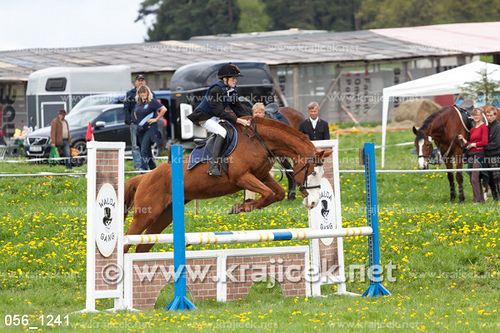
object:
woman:
[458, 108, 489, 204]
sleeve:
[476, 124, 488, 148]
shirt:
[464, 123, 488, 153]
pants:
[470, 156, 485, 203]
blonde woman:
[131, 84, 167, 174]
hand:
[147, 118, 158, 125]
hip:
[150, 119, 165, 132]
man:
[298, 101, 331, 140]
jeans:
[200, 116, 235, 164]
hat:
[217, 62, 243, 80]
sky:
[0, 0, 158, 52]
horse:
[412, 104, 499, 204]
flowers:
[404, 197, 500, 249]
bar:
[123, 226, 374, 246]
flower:
[240, 319, 246, 323]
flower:
[270, 220, 277, 226]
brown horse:
[124, 115, 334, 253]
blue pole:
[361, 142, 392, 298]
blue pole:
[163, 144, 198, 312]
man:
[50, 110, 72, 169]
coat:
[50, 116, 72, 145]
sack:
[48, 145, 61, 168]